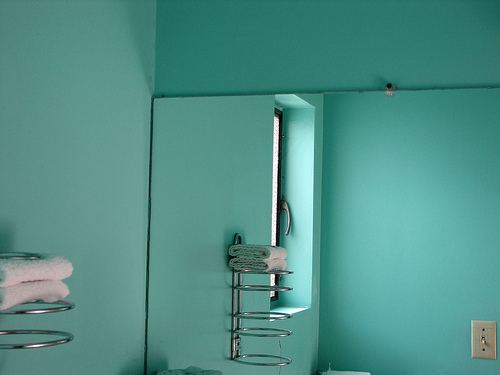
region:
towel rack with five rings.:
[224, 229, 291, 374]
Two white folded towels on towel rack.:
[227, 234, 292, 277]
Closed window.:
[272, 96, 312, 317]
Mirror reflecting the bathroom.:
[154, 96, 492, 372]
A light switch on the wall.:
[468, 316, 498, 357]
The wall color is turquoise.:
[160, 2, 482, 87]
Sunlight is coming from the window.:
[265, 104, 309, 298]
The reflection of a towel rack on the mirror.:
[227, 227, 286, 372]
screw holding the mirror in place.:
[382, 81, 394, 93]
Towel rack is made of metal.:
[0, 244, 85, 365]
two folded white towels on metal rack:
[221, 238, 291, 273]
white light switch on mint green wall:
[464, 313, 496, 365]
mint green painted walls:
[153, 95, 495, 371]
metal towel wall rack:
[228, 265, 294, 372]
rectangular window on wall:
[270, 105, 299, 308]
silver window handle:
[276, 198, 295, 238]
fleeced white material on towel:
[14, 261, 54, 276]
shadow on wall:
[107, 354, 208, 374]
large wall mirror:
[126, 95, 496, 368]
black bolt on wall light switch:
[479, 323, 490, 333]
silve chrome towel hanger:
[217, 225, 300, 372]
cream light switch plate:
[461, 306, 499, 365]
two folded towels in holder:
[2, 229, 94, 333]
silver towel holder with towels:
[1, 240, 98, 358]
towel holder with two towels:
[0, 242, 89, 366]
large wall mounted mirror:
[133, 80, 497, 367]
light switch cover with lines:
[466, 300, 493, 361]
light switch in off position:
[461, 306, 499, 366]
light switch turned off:
[458, 312, 498, 372]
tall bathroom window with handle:
[243, 79, 338, 361]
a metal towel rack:
[227, 231, 297, 367]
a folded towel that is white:
[1, 255, 71, 282]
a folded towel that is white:
[1, 281, 69, 310]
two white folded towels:
[226, 241, 290, 273]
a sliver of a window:
[271, 109, 282, 304]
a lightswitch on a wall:
[467, 318, 497, 359]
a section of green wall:
[145, 95, 318, 374]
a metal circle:
[233, 280, 291, 291]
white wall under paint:
[322, 361, 372, 373]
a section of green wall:
[154, 1, 496, 91]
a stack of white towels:
[226, 240, 290, 274]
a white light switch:
[469, 315, 499, 355]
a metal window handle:
[276, 196, 296, 238]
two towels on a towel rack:
[1, 252, 83, 357]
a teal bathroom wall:
[141, 89, 326, 374]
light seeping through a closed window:
[271, 106, 286, 299]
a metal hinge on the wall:
[380, 82, 397, 96]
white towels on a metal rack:
[0, 259, 75, 309]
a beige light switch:
[471, 320, 496, 360]